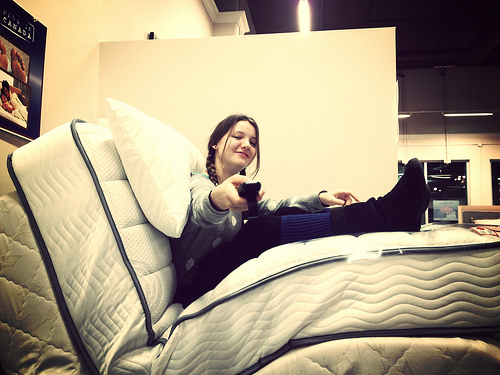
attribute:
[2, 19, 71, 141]
poster — written, hanging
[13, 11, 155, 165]
wall — white, store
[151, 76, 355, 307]
girl — holding, wearing, held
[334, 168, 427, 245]
sock — blue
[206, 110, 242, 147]
hair — dark, braided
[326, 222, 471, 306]
mattress — white, folded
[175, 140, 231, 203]
pigtails — hairstyle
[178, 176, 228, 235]
shirt — gray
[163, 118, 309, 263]
woman — young, hold, wearing, use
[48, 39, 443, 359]
picture — mattress, wall, divider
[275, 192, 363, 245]
pant — blue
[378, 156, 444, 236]
shoe — black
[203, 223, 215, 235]
sweater — grey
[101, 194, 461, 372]
bed — showroom, adjustable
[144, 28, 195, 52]
fixture — light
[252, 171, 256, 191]
remote — black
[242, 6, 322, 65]
light — ceiling